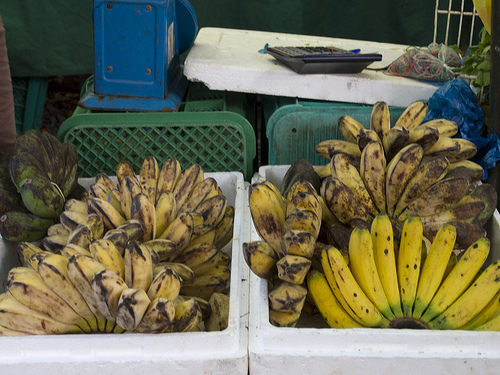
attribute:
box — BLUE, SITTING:
[78, 59, 179, 120]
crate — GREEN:
[45, 112, 263, 198]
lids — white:
[184, 99, 224, 101]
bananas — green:
[5, 119, 88, 239]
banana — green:
[29, 176, 73, 213]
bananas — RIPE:
[12, 101, 232, 336]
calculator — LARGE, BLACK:
[272, 49, 381, 97]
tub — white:
[227, 243, 471, 373]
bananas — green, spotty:
[15, 136, 139, 264]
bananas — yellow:
[289, 210, 479, 337]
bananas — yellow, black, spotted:
[310, 210, 490, 363]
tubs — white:
[154, 182, 305, 351]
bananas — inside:
[49, 148, 260, 338]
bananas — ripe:
[310, 227, 488, 336]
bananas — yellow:
[310, 210, 490, 338]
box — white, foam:
[228, 161, 418, 372]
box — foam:
[177, 28, 397, 103]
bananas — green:
[9, 133, 119, 253]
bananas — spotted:
[250, 128, 493, 303]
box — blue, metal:
[71, 14, 177, 104]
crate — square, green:
[80, 92, 252, 184]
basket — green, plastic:
[56, 84, 257, 178]